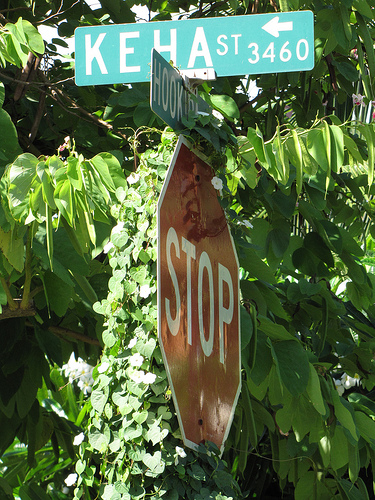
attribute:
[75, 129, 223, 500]
ivy — growing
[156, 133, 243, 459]
sign — red, white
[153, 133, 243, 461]
stop sign — red, white, facing right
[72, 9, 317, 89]
sign — bluish, green, white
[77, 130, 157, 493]
leaves — green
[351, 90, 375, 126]
flowers — red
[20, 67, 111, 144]
sticks — brown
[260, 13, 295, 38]
arrow — white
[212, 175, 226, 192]
flower — white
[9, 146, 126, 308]
leaves — large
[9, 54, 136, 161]
branches — tree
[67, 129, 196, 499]
vine — growing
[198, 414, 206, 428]
screw — black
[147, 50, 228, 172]
street sign — rectangular, bluish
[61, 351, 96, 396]
flowers — white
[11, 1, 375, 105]
sky — bright